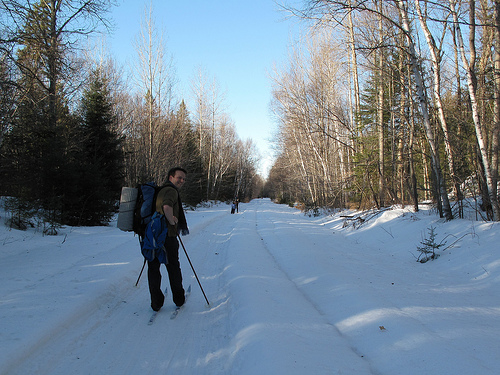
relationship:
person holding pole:
[142, 162, 188, 308] [174, 229, 212, 310]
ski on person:
[171, 282, 193, 321] [142, 162, 188, 308]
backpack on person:
[136, 179, 178, 235] [142, 162, 188, 308]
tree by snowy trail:
[135, 11, 164, 206] [74, 165, 232, 369]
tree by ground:
[135, 11, 164, 206] [0, 197, 497, 372]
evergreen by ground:
[68, 71, 129, 231] [0, 197, 497, 372]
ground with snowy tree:
[0, 199, 496, 372] [135, 11, 164, 206]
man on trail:
[229, 195, 241, 215] [74, 165, 232, 369]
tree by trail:
[135, 11, 164, 206] [74, 165, 232, 369]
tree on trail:
[135, 11, 164, 206] [74, 165, 232, 369]